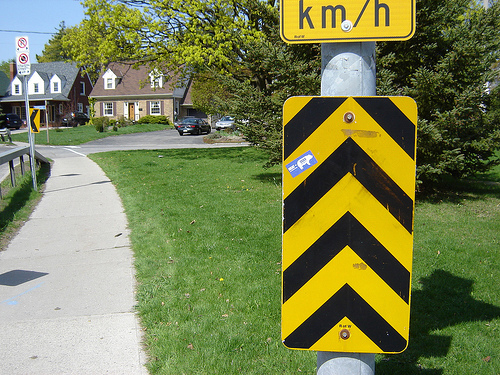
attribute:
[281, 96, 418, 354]
sign — yellow, black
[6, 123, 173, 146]
lawn — green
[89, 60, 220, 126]
house — brown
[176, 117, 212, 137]
car — small, parked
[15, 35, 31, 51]
sign — no parking sign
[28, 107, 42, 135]
sign — warning sign, yellow, black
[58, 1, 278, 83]
flowers — yellow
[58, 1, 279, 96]
tree — green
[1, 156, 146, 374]
sidewalk — gray, concrete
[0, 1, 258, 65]
sky — blue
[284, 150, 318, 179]
sticker — blue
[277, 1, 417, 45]
sign — black, yellow, speed limit sign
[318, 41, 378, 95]
pole — gray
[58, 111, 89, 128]
car — parked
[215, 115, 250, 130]
car — parked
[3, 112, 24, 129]
car — parked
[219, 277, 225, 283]
dandelion — yellow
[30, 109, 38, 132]
arrow — black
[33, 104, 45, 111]
street sign — blue, white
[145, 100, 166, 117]
shutters — brown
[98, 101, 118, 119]
shutters — brown